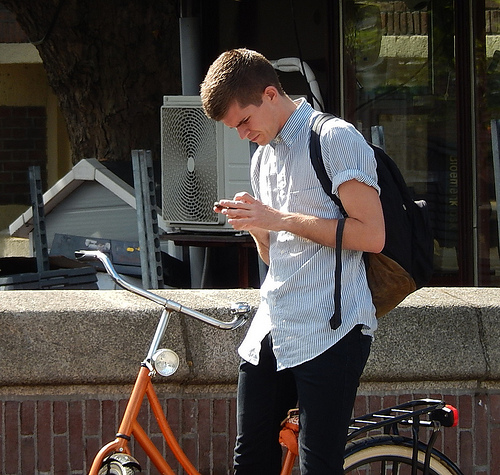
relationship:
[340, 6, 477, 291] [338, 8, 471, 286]
reflections in glass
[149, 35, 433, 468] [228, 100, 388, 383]
man in shirt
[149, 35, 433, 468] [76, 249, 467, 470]
man on bike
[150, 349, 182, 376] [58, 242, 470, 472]
front light of bicycle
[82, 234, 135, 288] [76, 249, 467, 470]
right handlebar of bike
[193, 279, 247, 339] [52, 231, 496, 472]
left handlebar of bike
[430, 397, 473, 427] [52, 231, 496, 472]
back reflector of bike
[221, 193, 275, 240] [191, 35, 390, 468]
left hand of man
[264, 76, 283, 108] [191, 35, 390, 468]
left ear of man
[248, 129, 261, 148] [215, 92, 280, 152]
mouth on man's face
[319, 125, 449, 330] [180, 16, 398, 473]
black bookbag on man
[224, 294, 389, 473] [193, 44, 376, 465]
black pants on man